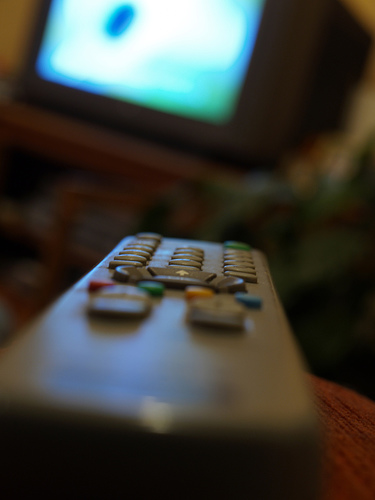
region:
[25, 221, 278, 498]
long grey remote in front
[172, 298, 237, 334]
grey button on remote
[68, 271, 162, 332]
grey buttons on remote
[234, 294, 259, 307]
blue button on remote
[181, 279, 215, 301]
yellow button on remote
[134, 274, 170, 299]
green button on remote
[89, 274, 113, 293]
red button on remote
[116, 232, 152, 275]
line of grey buttons on remote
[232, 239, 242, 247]
small green button on remote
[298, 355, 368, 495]
brown table below remote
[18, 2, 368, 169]
An out of focus television screen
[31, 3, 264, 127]
A blue glowing screen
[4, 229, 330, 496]
A television remote control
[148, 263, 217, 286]
The up arrow key on a television remote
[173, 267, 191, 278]
A small white arrow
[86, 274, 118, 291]
A red button on a television remote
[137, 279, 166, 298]
A green button on a television remote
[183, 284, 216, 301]
A yellow button on a television remote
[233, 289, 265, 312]
A blue button on a television remote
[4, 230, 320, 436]
A television remote partially in focus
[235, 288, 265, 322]
Blue button on remote control.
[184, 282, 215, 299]
Yellow button on remote control.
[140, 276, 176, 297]
Green button on remote control.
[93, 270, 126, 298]
Red button on remote control.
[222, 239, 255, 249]
Green button on remote control.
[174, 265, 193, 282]
White arrow on button on remote.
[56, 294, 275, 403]
Gray remote control sitting on brown surface.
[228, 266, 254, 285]
Gray button on remote control.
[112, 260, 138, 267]
Gray button on remote control.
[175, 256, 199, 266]
Gray button on remote control.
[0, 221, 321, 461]
remote control gone blurry as it nears viewer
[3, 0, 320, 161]
a television in the near distance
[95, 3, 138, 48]
.....with a great blue abstract amoebalike spot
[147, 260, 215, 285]
a white up arrow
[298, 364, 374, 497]
burnt red-orange cloth, probably velour or similar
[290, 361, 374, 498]
i think it's the armrest of a recliner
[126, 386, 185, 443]
a white scrape on grey plastic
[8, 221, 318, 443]
TV remote with buttons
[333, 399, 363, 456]
brown table under tv remote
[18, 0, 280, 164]
TV in background of remote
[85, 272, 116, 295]
red button on tv remote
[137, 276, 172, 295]
green button tv remote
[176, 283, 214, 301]
yellow button on tv remote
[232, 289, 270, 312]
blue button on tv remote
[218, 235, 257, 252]
green button on tv remote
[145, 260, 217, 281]
tv remote button with arrow on it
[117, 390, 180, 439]
IR light on tv remote